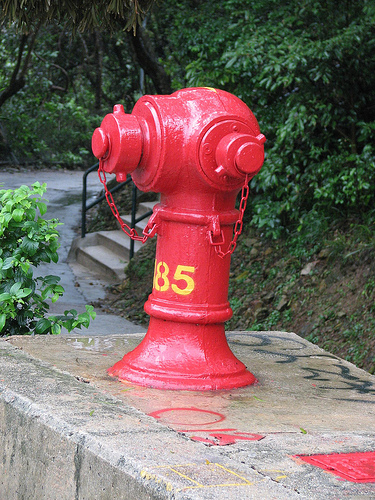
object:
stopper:
[198, 119, 266, 187]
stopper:
[92, 102, 163, 187]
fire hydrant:
[92, 85, 267, 391]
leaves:
[0, 0, 375, 343]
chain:
[97, 156, 148, 245]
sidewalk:
[0, 168, 147, 336]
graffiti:
[225, 329, 375, 405]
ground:
[0, 168, 149, 336]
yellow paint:
[152, 259, 194, 296]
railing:
[80, 164, 152, 262]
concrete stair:
[76, 243, 127, 284]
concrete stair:
[96, 229, 141, 262]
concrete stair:
[115, 214, 156, 245]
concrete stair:
[138, 202, 158, 215]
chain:
[207, 173, 250, 260]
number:
[171, 265, 195, 296]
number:
[155, 260, 170, 292]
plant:
[0, 178, 97, 337]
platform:
[0, 329, 375, 500]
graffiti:
[146, 405, 264, 446]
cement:
[0, 331, 375, 500]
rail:
[80, 155, 153, 264]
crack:
[0, 337, 304, 499]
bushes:
[149, 0, 375, 259]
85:
[155, 261, 195, 296]